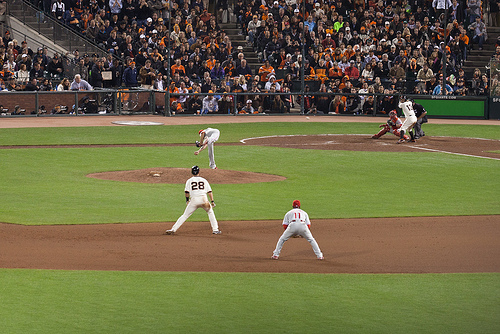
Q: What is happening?
A: A baseball game.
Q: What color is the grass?
A: Green.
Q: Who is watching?
A: Fans.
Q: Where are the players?
A: On the field.